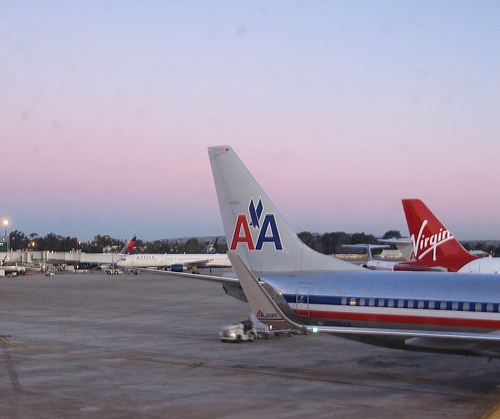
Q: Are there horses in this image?
A: No, there are no horses.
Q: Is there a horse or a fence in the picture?
A: No, there are no horses or fences.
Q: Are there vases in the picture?
A: No, there are no vases.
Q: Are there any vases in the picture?
A: No, there are no vases.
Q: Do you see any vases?
A: No, there are no vases.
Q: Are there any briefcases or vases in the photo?
A: No, there are no vases or briefcases.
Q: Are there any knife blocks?
A: No, there are no knife blocks.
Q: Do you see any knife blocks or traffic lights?
A: No, there are no knife blocks or traffic lights.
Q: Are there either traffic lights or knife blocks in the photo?
A: No, there are no knife blocks or traffic lights.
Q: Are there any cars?
A: No, there are no cars.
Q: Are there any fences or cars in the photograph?
A: No, there are no cars or fences.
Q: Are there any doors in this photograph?
A: Yes, there is a door.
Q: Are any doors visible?
A: Yes, there is a door.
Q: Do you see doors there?
A: Yes, there is a door.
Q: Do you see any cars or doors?
A: Yes, there is a door.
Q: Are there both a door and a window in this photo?
A: Yes, there are both a door and a window.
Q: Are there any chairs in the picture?
A: No, there are no chairs.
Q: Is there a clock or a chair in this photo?
A: No, there are no chairs or clocks.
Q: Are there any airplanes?
A: Yes, there is an airplane.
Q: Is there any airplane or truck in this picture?
A: Yes, there is an airplane.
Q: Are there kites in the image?
A: No, there are no kites.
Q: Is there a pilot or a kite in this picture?
A: No, there are no kites or pilots.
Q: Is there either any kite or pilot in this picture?
A: No, there are no kites or pilots.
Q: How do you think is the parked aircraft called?
A: The aircraft is an airplane.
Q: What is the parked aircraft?
A: The aircraft is an airplane.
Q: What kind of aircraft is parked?
A: The aircraft is an airplane.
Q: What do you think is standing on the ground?
A: The plane is standing on the ground.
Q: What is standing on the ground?
A: The plane is standing on the ground.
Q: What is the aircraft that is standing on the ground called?
A: The aircraft is an airplane.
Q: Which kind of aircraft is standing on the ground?
A: The aircraft is an airplane.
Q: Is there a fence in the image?
A: No, there are no fences.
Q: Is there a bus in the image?
A: No, there are no buses.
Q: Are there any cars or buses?
A: No, there are no buses or cars.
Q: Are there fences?
A: No, there are no fences.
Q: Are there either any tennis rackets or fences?
A: No, there are no fences or tennis rackets.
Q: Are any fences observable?
A: No, there are no fences.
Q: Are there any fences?
A: No, there are no fences.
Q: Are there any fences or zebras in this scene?
A: No, there are no fences or zebras.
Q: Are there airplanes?
A: Yes, there is an airplane.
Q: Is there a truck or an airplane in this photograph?
A: Yes, there is an airplane.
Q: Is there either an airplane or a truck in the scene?
A: Yes, there is an airplane.